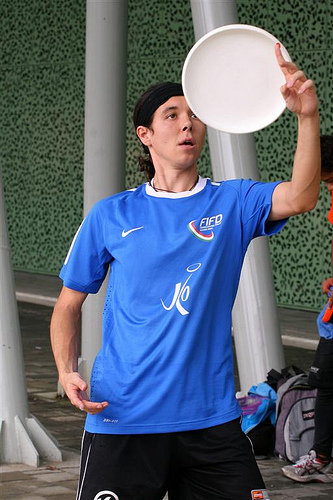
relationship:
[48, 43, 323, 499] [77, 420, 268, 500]
man wearing shorts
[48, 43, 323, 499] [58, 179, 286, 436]
man wearing a shirt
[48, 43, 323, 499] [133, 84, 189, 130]
man wearing a head band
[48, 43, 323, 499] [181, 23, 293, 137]
man holding frisbee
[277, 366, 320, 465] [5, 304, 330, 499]
backpack on ground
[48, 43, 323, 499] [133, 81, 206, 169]
man has a head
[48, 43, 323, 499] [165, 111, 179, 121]
man has an eye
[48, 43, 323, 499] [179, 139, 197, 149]
man has a mouth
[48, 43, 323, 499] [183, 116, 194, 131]
man has a nose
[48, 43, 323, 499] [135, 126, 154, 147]
man has an ear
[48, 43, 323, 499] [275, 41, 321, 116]
man has a hand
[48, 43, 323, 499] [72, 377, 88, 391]
man has a thumb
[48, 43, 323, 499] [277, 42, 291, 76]
man has a finger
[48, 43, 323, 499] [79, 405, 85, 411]
man has a fingernail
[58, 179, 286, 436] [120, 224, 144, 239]
shirt has a logo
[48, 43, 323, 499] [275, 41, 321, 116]
boy has a hand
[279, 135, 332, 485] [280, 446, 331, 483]
person has a shoe